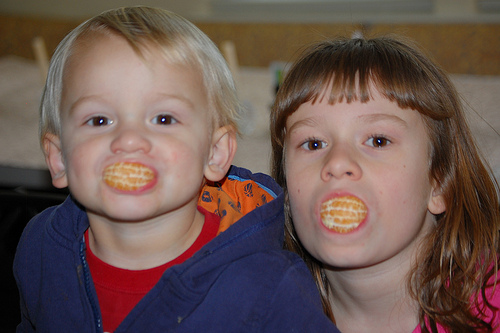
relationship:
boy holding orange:
[2, 6, 338, 332] [99, 162, 154, 190]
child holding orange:
[270, 34, 499, 331] [321, 195, 363, 227]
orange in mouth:
[99, 162, 154, 190] [103, 158, 163, 194]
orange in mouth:
[321, 195, 363, 227] [308, 188, 372, 236]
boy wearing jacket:
[14, 1, 328, 324] [13, 167, 336, 326]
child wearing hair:
[270, 34, 500, 333] [268, 28, 499, 325]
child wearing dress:
[270, 34, 500, 333] [412, 252, 500, 329]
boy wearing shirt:
[14, 1, 328, 324] [78, 208, 221, 323]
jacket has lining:
[13, 167, 336, 326] [203, 174, 272, 232]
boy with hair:
[14, 1, 328, 324] [36, 4, 241, 143]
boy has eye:
[14, 1, 328, 324] [147, 107, 184, 124]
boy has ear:
[14, 1, 328, 324] [202, 117, 239, 184]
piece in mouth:
[105, 157, 156, 187] [103, 158, 163, 194]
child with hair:
[270, 34, 500, 333] [268, 28, 499, 325]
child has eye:
[270, 34, 500, 333] [292, 132, 326, 156]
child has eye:
[270, 34, 500, 333] [361, 128, 398, 152]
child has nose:
[270, 34, 500, 333] [316, 130, 361, 178]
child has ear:
[270, 34, 500, 333] [429, 131, 455, 216]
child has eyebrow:
[270, 34, 500, 333] [354, 108, 411, 127]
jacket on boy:
[13, 167, 336, 326] [14, 1, 328, 324]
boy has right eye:
[14, 1, 328, 324] [79, 110, 111, 130]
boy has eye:
[14, 1, 328, 324] [147, 111, 184, 127]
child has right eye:
[270, 34, 500, 333] [292, 132, 326, 156]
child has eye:
[270, 34, 500, 333] [296, 136, 329, 153]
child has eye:
[270, 34, 500, 333] [147, 111, 184, 127]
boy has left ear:
[14, 1, 328, 324] [41, 130, 81, 192]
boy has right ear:
[14, 1, 328, 324] [49, 129, 75, 195]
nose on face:
[110, 105, 153, 156] [58, 36, 213, 223]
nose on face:
[316, 130, 361, 178] [286, 98, 422, 262]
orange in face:
[321, 195, 363, 227] [286, 98, 422, 262]